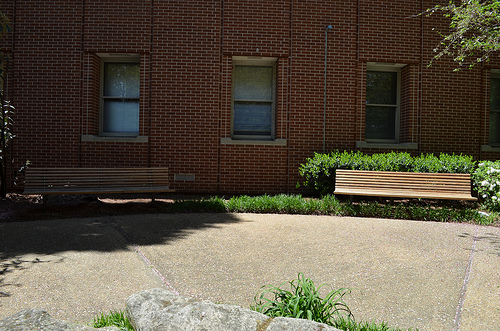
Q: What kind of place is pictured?
A: It is a walkway.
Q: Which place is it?
A: It is a walkway.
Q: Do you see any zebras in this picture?
A: No, there are no zebras.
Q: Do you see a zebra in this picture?
A: No, there are no zebras.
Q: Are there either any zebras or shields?
A: No, there are no zebras or shields.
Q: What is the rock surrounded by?
A: The rock is surrounded by the grass.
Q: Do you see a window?
A: Yes, there is a window.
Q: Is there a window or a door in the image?
A: Yes, there is a window.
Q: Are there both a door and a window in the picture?
A: No, there is a window but no doors.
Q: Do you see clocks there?
A: No, there are no clocks.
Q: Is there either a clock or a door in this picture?
A: No, there are no clocks or doors.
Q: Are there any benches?
A: Yes, there is a bench.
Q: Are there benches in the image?
A: Yes, there is a bench.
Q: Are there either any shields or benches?
A: Yes, there is a bench.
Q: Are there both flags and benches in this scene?
A: No, there is a bench but no flags.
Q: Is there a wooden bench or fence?
A: Yes, there is a wood bench.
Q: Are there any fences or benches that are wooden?
A: Yes, the bench is wooden.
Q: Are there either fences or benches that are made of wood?
A: Yes, the bench is made of wood.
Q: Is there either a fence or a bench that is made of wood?
A: Yes, the bench is made of wood.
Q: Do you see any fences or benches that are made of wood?
A: Yes, the bench is made of wood.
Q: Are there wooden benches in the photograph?
A: Yes, there is a wood bench.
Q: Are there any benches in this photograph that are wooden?
A: Yes, there is a bench that is wooden.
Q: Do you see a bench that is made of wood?
A: Yes, there is a bench that is made of wood.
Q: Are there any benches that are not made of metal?
A: Yes, there is a bench that is made of wood.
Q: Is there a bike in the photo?
A: No, there are no bikes.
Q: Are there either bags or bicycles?
A: No, there are no bicycles or bags.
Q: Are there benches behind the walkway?
A: Yes, there is a bench behind the walkway.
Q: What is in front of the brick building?
A: The bench is in front of the building.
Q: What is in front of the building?
A: The bench is in front of the building.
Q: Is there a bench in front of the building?
A: Yes, there is a bench in front of the building.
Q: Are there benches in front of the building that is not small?
A: Yes, there is a bench in front of the building.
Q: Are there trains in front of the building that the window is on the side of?
A: No, there is a bench in front of the building.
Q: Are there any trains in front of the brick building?
A: No, there is a bench in front of the building.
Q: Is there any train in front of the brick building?
A: No, there is a bench in front of the building.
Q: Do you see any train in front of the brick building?
A: No, there is a bench in front of the building.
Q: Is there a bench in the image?
A: Yes, there is a bench.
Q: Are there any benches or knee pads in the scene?
A: Yes, there is a bench.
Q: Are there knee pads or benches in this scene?
A: Yes, there is a bench.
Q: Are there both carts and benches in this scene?
A: No, there is a bench but no carts.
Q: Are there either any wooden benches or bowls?
A: Yes, there is a wood bench.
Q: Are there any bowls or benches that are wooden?
A: Yes, the bench is wooden.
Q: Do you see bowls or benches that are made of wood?
A: Yes, the bench is made of wood.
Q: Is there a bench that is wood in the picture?
A: Yes, there is a wood bench.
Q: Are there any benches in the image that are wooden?
A: Yes, there is a bench that is wooden.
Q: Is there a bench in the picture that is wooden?
A: Yes, there is a bench that is wooden.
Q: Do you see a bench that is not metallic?
A: Yes, there is a wooden bench.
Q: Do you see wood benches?
A: Yes, there is a bench that is made of wood.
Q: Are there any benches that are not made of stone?
A: Yes, there is a bench that is made of wood.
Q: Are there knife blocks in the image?
A: No, there are no knife blocks.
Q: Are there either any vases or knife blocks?
A: No, there are no knife blocks or vases.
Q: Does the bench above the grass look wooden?
A: Yes, the bench is wooden.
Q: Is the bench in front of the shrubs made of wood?
A: Yes, the bench is made of wood.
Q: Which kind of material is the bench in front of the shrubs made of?
A: The bench is made of wood.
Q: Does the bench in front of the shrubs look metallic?
A: No, the bench is wooden.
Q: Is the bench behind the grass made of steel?
A: No, the bench is made of wood.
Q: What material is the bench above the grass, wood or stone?
A: The bench is made of wood.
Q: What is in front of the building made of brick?
A: The bench is in front of the building.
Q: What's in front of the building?
A: The bench is in front of the building.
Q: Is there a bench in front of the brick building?
A: Yes, there is a bench in front of the building.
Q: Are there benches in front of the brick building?
A: Yes, there is a bench in front of the building.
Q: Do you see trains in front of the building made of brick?
A: No, there is a bench in front of the building.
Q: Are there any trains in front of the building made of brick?
A: No, there is a bench in front of the building.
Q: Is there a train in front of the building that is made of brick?
A: No, there is a bench in front of the building.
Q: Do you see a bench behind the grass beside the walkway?
A: Yes, there is a bench behind the grass.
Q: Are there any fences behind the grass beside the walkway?
A: No, there is a bench behind the grass.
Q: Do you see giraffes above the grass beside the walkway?
A: No, there is a bench above the grass.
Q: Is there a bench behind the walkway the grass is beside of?
A: Yes, there is a bench behind the walkway.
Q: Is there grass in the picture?
A: Yes, there is grass.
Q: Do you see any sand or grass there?
A: Yes, there is grass.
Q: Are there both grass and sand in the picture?
A: No, there is grass but no sand.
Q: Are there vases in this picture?
A: No, there are no vases.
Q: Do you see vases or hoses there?
A: No, there are no vases or hoses.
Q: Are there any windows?
A: Yes, there is a window.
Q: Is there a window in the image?
A: Yes, there is a window.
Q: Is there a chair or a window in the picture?
A: Yes, there is a window.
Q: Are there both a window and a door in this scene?
A: No, there is a window but no doors.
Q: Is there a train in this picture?
A: No, there are no trains.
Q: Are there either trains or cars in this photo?
A: No, there are no trains or cars.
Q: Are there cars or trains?
A: No, there are no trains or cars.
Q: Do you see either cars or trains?
A: No, there are no trains or cars.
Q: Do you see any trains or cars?
A: No, there are no trains or cars.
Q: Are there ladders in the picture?
A: No, there are no ladders.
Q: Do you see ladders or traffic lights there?
A: No, there are no ladders or traffic lights.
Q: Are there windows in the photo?
A: Yes, there is a window.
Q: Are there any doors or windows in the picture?
A: Yes, there is a window.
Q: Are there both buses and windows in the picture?
A: No, there is a window but no buses.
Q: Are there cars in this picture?
A: No, there are no cars.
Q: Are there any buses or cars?
A: No, there are no cars or buses.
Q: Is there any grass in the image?
A: Yes, there is grass.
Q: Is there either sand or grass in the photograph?
A: Yes, there is grass.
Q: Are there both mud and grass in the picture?
A: No, there is grass but no mud.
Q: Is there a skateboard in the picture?
A: No, there are no skateboards.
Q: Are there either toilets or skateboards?
A: No, there are no skateboards or toilets.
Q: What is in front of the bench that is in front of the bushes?
A: The grass is in front of the bench.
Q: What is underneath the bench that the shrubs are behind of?
A: The grass is underneath the bench.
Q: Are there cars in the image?
A: No, there are no cars.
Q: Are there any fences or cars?
A: No, there are no cars or fences.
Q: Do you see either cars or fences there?
A: No, there are no cars or fences.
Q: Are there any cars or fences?
A: No, there are no cars or fences.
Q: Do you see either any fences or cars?
A: No, there are no cars or fences.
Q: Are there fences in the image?
A: No, there are no fences.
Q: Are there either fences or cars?
A: No, there are no fences or cars.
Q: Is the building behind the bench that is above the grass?
A: Yes, the building is behind the bench.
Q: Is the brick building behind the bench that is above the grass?
A: Yes, the building is behind the bench.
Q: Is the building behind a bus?
A: No, the building is behind the bench.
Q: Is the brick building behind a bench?
A: Yes, the building is behind a bench.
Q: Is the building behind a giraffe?
A: No, the building is behind a bench.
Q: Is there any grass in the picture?
A: Yes, there is grass.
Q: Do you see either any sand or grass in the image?
A: Yes, there is grass.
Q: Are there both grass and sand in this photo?
A: No, there is grass but no sand.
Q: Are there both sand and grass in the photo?
A: No, there is grass but no sand.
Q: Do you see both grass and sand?
A: No, there is grass but no sand.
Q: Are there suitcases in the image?
A: No, there are no suitcases.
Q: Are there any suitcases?
A: No, there are no suitcases.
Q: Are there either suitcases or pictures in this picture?
A: No, there are no suitcases or pictures.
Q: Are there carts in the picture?
A: No, there are no carts.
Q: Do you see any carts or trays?
A: No, there are no carts or trays.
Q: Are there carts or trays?
A: No, there are no carts or trays.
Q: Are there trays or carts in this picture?
A: No, there are no carts or trays.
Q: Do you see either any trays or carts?
A: No, there are no carts or trays.